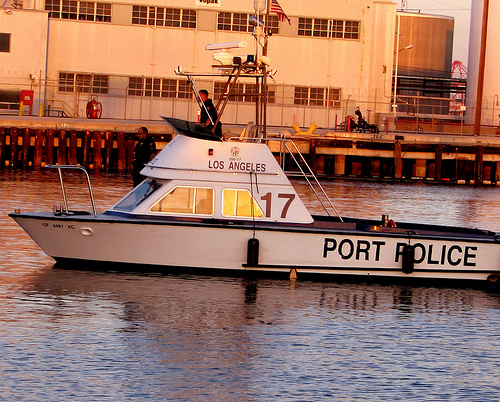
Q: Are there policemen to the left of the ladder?
A: Yes, there is a policeman to the left of the ladder.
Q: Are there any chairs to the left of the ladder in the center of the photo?
A: No, there is a policeman to the left of the ladder.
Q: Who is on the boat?
A: The police officer is on the boat.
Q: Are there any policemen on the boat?
A: Yes, there is a policeman on the boat.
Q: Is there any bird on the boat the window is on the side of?
A: No, there is a policeman on the boat.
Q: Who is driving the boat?
A: The police officer is driving the boat.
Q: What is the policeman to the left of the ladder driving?
A: The police officer is driving the boat.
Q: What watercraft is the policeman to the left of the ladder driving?
A: The policeman is driving the boat.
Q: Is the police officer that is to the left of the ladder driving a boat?
A: Yes, the police officer is driving a boat.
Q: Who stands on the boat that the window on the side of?
A: The police officer stands on the boat.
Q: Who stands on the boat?
A: The police officer stands on the boat.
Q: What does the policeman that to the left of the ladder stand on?
A: The police officer stands on the boat.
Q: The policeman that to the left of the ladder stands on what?
A: The police officer stands on the boat.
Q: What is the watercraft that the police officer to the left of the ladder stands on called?
A: The watercraft is a boat.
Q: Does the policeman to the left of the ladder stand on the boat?
A: Yes, the policeman stands on the boat.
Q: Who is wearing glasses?
A: The policeman is wearing glasses.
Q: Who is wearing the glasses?
A: The policeman is wearing glasses.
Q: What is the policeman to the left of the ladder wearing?
A: The policeman is wearing glasses.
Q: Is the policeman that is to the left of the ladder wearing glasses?
A: Yes, the police officer is wearing glasses.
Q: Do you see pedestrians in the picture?
A: No, there are no pedestrians.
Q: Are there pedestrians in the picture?
A: No, there are no pedestrians.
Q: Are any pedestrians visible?
A: No, there are no pedestrians.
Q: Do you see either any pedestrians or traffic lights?
A: No, there are no pedestrians or traffic lights.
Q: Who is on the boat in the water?
A: The police officer is on the boat.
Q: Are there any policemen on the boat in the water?
A: Yes, there is a policeman on the boat.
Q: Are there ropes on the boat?
A: No, there is a policeman on the boat.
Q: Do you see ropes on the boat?
A: No, there is a policeman on the boat.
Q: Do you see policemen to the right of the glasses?
A: Yes, there is a policeman to the right of the glasses.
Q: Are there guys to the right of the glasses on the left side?
A: No, there is a policeman to the right of the glasses.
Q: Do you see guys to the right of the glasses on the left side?
A: No, there is a policeman to the right of the glasses.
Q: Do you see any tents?
A: No, there are no tents.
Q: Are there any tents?
A: No, there are no tents.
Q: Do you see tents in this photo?
A: No, there are no tents.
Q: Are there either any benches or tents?
A: No, there are no tents or benches.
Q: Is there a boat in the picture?
A: Yes, there is a boat.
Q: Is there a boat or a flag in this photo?
A: Yes, there is a boat.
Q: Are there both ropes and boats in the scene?
A: No, there is a boat but no ropes.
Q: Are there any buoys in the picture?
A: No, there are no buoys.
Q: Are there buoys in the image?
A: No, there are no buoys.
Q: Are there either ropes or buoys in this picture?
A: No, there are no buoys or ropes.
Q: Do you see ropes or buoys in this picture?
A: No, there are no buoys or ropes.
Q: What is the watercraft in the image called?
A: The watercraft is a boat.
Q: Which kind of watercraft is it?
A: The watercraft is a boat.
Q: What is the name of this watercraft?
A: This is a boat.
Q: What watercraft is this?
A: This is a boat.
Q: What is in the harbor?
A: The boat is in the harbor.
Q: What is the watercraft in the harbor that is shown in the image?
A: The watercraft is a boat.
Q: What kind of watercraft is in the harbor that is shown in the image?
A: The watercraft is a boat.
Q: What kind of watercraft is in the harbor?
A: The watercraft is a boat.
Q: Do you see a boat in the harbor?
A: Yes, there is a boat in the harbor.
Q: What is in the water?
A: The boat is in the water.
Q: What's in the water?
A: The boat is in the water.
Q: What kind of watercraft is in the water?
A: The watercraft is a boat.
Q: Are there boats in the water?
A: Yes, there is a boat in the water.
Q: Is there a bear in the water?
A: No, there is a boat in the water.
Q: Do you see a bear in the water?
A: No, there is a boat in the water.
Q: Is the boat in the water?
A: Yes, the boat is in the water.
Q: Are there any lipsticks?
A: No, there are no lipsticks.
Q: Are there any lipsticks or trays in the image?
A: No, there are no lipsticks or trays.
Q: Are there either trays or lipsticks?
A: No, there are no lipsticks or trays.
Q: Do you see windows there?
A: Yes, there is a window.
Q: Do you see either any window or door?
A: Yes, there is a window.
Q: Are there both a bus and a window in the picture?
A: No, there is a window but no buses.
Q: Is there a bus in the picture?
A: No, there are no buses.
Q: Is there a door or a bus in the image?
A: No, there are no buses or doors.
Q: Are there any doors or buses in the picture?
A: No, there are no buses or doors.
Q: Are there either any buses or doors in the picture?
A: No, there are no buses or doors.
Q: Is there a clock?
A: No, there are no clocks.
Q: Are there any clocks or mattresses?
A: No, there are no clocks or mattresses.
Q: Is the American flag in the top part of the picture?
A: Yes, the American flag is in the top of the image.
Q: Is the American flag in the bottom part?
A: No, the American flag is in the top of the image.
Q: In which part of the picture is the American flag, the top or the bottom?
A: The American flag is in the top of the image.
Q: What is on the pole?
A: The American flag is on the pole.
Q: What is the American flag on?
A: The American flag is on the pole.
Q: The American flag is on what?
A: The American flag is on the pole.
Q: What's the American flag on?
A: The American flag is on the pole.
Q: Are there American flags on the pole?
A: Yes, there is an American flag on the pole.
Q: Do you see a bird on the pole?
A: No, there is an American flag on the pole.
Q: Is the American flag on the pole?
A: Yes, the American flag is on the pole.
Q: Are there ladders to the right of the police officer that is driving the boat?
A: Yes, there is a ladder to the right of the police officer.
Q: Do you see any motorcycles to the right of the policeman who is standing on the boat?
A: No, there is a ladder to the right of the policeman.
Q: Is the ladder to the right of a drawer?
A: No, the ladder is to the right of a policeman.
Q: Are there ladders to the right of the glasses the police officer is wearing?
A: Yes, there is a ladder to the right of the glasses.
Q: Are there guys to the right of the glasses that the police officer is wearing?
A: No, there is a ladder to the right of the glasses.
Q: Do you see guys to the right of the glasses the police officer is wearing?
A: No, there is a ladder to the right of the glasses.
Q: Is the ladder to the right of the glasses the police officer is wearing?
A: Yes, the ladder is to the right of the glasses.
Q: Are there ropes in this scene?
A: No, there are no ropes.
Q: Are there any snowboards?
A: No, there are no snowboards.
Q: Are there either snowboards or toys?
A: No, there are no snowboards or toys.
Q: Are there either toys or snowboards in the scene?
A: No, there are no snowboards or toys.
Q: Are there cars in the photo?
A: No, there are no cars.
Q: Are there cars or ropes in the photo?
A: No, there are no cars or ropes.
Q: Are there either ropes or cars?
A: No, there are no cars or ropes.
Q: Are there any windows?
A: Yes, there is a window.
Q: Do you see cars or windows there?
A: Yes, there is a window.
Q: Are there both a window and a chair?
A: No, there is a window but no chairs.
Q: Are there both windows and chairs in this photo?
A: No, there is a window but no chairs.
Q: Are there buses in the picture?
A: No, there are no buses.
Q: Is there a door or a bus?
A: No, there are no buses or doors.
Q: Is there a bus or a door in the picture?
A: No, there are no buses or doors.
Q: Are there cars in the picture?
A: No, there are no cars.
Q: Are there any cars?
A: No, there are no cars.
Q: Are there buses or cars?
A: No, there are no cars or buses.